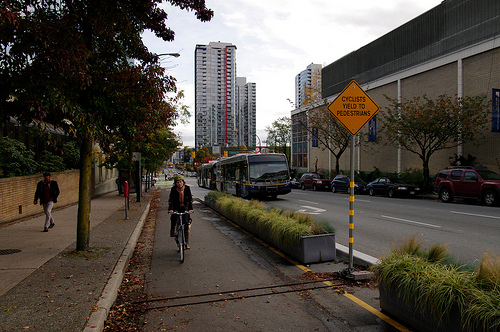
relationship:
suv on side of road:
[430, 163, 499, 210] [170, 167, 500, 277]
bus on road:
[215, 150, 294, 202] [170, 167, 500, 277]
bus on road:
[192, 158, 216, 191] [170, 167, 500, 277]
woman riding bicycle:
[166, 172, 193, 250] [167, 209, 190, 264]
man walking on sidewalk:
[31, 169, 62, 233] [2, 181, 136, 296]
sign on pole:
[327, 77, 384, 136] [348, 132, 357, 276]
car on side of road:
[363, 172, 421, 199] [170, 167, 500, 277]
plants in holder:
[202, 187, 335, 243] [204, 194, 339, 268]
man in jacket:
[31, 169, 62, 233] [33, 178, 60, 206]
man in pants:
[31, 169, 62, 233] [36, 195, 57, 227]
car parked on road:
[363, 172, 421, 199] [170, 167, 500, 277]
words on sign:
[335, 94, 375, 120] [327, 77, 384, 136]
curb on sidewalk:
[82, 193, 154, 329] [2, 181, 136, 296]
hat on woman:
[171, 170, 186, 182] [166, 172, 193, 250]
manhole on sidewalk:
[1, 245, 23, 258] [2, 181, 136, 296]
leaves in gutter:
[107, 184, 160, 329] [102, 184, 153, 328]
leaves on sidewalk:
[107, 184, 160, 329] [2, 181, 136, 296]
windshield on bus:
[246, 159, 289, 183] [215, 150, 294, 202]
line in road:
[383, 212, 444, 231] [170, 167, 500, 277]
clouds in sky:
[261, 11, 378, 66] [1, 0, 441, 148]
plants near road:
[202, 187, 335, 243] [170, 167, 500, 277]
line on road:
[383, 212, 444, 231] [170, 167, 500, 277]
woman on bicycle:
[166, 172, 193, 250] [167, 209, 190, 264]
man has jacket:
[31, 169, 62, 233] [33, 178, 60, 206]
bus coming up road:
[215, 150, 294, 202] [170, 167, 500, 277]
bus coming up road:
[192, 158, 216, 191] [170, 167, 500, 277]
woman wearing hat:
[166, 172, 193, 250] [171, 170, 186, 182]